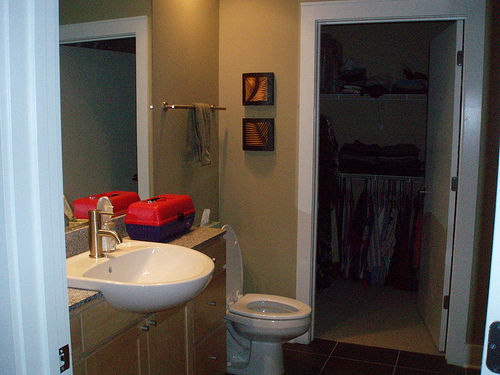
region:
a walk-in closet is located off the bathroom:
[304, 9, 459, 360]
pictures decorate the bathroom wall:
[237, 67, 281, 158]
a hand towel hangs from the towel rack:
[182, 101, 214, 167]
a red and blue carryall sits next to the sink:
[121, 190, 201, 243]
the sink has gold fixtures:
[86, 205, 124, 260]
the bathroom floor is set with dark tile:
[286, 335, 466, 372]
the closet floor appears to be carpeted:
[308, 274, 440, 355]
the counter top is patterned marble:
[64, 210, 228, 309]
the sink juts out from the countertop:
[66, 235, 214, 317]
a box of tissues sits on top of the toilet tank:
[194, 203, 225, 233]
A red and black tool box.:
[123, 190, 205, 240]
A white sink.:
[67, 213, 222, 323]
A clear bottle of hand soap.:
[98, 204, 123, 259]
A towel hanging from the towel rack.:
[165, 89, 232, 174]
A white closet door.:
[298, 3, 465, 370]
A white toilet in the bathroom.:
[209, 214, 314, 373]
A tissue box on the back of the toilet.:
[192, 203, 231, 241]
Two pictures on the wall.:
[228, 68, 282, 175]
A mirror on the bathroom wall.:
[58, 13, 157, 232]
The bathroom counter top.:
[64, 193, 245, 315]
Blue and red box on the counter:
[122, 192, 199, 240]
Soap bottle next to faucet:
[100, 202, 119, 249]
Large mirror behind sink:
[57, 0, 152, 257]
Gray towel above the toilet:
[193, 102, 214, 167]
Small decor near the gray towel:
[240, 115, 275, 149]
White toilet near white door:
[217, 221, 312, 373]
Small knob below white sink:
[142, 323, 149, 333]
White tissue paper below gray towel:
[198, 205, 213, 225]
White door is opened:
[419, 20, 461, 353]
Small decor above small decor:
[240, 70, 274, 106]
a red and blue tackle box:
[125, 194, 197, 239]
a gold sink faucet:
[87, 203, 121, 256]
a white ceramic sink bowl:
[64, 235, 215, 307]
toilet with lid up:
[215, 223, 313, 367]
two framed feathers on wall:
[232, 70, 279, 150]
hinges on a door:
[443, 48, 465, 310]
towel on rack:
[189, 101, 215, 168]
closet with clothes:
[322, 26, 428, 292]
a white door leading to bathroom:
[1, 0, 73, 374]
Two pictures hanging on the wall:
[233, 63, 285, 158]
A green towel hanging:
[189, 94, 216, 174]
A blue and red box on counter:
[121, 189, 203, 245]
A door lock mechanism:
[51, 338, 81, 373]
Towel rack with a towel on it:
[155, 87, 230, 175]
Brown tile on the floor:
[320, 338, 410, 371]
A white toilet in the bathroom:
[220, 219, 319, 373]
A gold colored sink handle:
[81, 202, 123, 264]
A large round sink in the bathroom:
[65, 208, 217, 310]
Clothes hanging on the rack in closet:
[321, 166, 431, 296]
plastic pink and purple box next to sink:
[63, 191, 215, 316]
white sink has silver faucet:
[66, 211, 217, 316]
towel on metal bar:
[160, 100, 227, 172]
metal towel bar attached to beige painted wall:
[148, 0, 227, 229]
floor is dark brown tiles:
[281, 335, 482, 373]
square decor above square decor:
[240, 69, 275, 153]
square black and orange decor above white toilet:
[217, 115, 311, 373]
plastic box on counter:
[66, 194, 228, 314]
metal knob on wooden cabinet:
[87, 318, 150, 373]